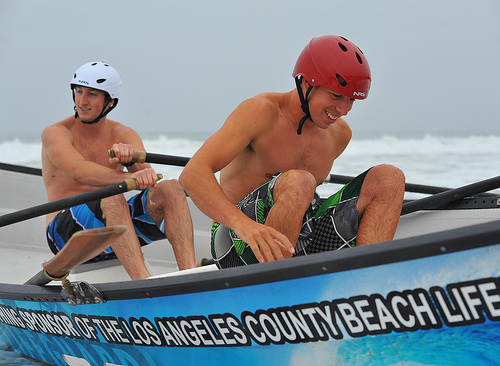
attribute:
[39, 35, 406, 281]
men — rowing boat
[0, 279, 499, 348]
words — white, black, on left side of boat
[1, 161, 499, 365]
boat — blue, grey, blue white, black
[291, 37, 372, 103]
helmet — for safety, being worn, red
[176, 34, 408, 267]
man — bare chested, shirtless, smiling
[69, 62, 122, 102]
helmet — white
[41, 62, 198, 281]
man — smiling, seated, shirtless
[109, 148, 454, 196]
oar — black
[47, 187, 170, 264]
swimming suit — patterned, blue, black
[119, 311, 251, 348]
los angeles — printed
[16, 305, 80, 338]
sponsor — printed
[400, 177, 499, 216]
oar — wooden, here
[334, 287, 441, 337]
beach — printed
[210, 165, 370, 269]
swimming suit — black green, whit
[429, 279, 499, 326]
life — printed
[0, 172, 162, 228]
oar — here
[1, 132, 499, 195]
waves — crashing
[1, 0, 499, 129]
sky — grey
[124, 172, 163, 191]
handle — brown